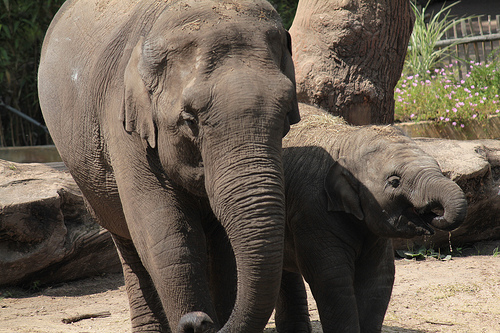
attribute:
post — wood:
[484, 16, 496, 87]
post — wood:
[474, 15, 487, 78]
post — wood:
[458, 14, 472, 82]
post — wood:
[447, 18, 466, 95]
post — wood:
[434, 17, 454, 82]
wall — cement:
[376, 135, 496, 246]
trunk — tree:
[284, 3, 414, 125]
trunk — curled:
[411, 177, 469, 228]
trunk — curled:
[181, 140, 302, 330]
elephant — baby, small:
[278, 132, 468, 325]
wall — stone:
[2, 134, 498, 280]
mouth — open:
[389, 194, 443, 244]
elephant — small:
[283, 120, 473, 331]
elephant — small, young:
[273, 96, 470, 330]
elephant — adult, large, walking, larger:
[33, 1, 303, 330]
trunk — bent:
[407, 168, 469, 231]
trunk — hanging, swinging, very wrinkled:
[173, 126, 289, 330]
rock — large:
[4, 149, 121, 291]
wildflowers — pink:
[405, 61, 498, 116]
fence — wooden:
[424, 14, 498, 70]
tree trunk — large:
[286, 3, 423, 125]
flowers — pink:
[416, 70, 476, 121]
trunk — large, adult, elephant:
[197, 132, 295, 303]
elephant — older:
[81, 45, 299, 293]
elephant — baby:
[315, 114, 465, 328]